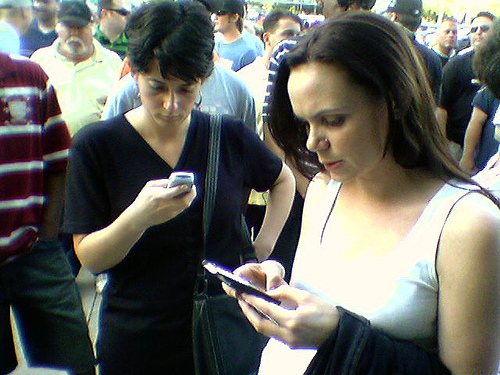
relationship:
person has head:
[213, 16, 500, 375] [260, 24, 463, 206]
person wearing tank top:
[213, 16, 500, 375] [276, 169, 473, 372]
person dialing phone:
[213, 16, 500, 375] [164, 163, 194, 193]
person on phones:
[213, 16, 500, 375] [164, 161, 281, 304]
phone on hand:
[198, 257, 280, 304] [221, 258, 283, 299]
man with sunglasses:
[212, 1, 257, 68] [210, 10, 227, 15]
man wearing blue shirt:
[212, 1, 257, 68] [211, 40, 263, 69]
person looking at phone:
[213, 16, 500, 375] [183, 239, 300, 327]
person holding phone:
[63, 0, 295, 375] [169, 171, 194, 193]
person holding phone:
[213, 16, 500, 375] [198, 257, 283, 305]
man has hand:
[22, 8, 133, 158] [30, 216, 65, 277]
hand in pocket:
[30, 216, 65, 277] [26, 229, 83, 294]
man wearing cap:
[22, 8, 131, 137] [52, 0, 90, 27]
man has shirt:
[233, 12, 320, 121] [227, 5, 317, 146]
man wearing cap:
[1, 0, 47, 57] [0, 1, 33, 10]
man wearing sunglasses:
[93, 0, 133, 62] [100, 5, 130, 17]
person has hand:
[213, 16, 500, 375] [241, 287, 328, 352]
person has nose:
[213, 16, 500, 375] [303, 119, 333, 154]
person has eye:
[213, 16, 500, 375] [312, 109, 350, 136]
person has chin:
[213, 16, 450, 370] [314, 155, 352, 187]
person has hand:
[213, 16, 500, 375] [111, 164, 218, 239]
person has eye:
[63, 0, 295, 373] [148, 78, 163, 92]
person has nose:
[63, 0, 295, 375] [161, 85, 182, 117]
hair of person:
[119, 0, 215, 84] [63, 0, 295, 375]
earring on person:
[195, 87, 204, 111] [63, 0, 295, 375]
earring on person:
[133, 80, 141, 104] [63, 0, 295, 375]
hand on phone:
[232, 287, 338, 348] [196, 251, 317, 329]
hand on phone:
[222, 260, 285, 296] [196, 251, 317, 329]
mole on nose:
[324, 135, 328, 141] [303, 122, 329, 152]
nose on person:
[303, 122, 329, 152] [213, 16, 500, 375]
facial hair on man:
[59, 36, 87, 63] [22, 1, 129, 126]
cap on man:
[50, 0, 90, 27] [22, 1, 129, 126]